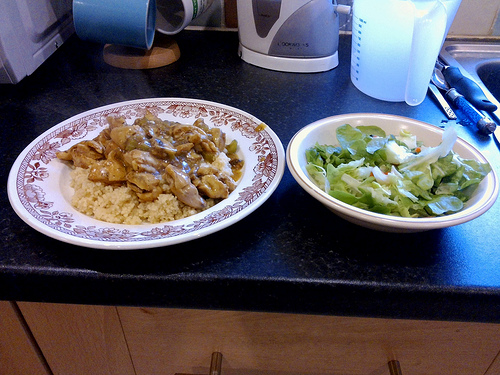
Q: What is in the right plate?
A: Salad.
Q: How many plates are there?
A: Two.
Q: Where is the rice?
A: Left plate.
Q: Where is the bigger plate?
A: The left one.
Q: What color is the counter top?
A: Black.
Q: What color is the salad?
A: Green.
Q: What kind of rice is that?
A: Brown rice.